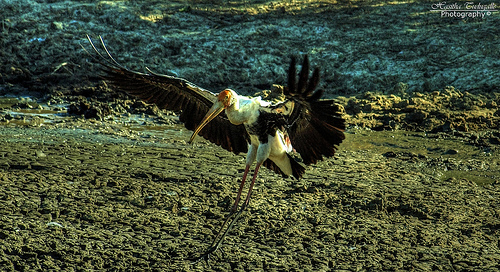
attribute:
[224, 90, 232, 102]
eye — black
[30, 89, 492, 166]
water — swirling, churning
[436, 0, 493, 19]
lettering — white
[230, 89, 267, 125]
patch — white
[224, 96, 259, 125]
chest — black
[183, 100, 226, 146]
beak — closed, long, pointy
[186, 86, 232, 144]
head — orange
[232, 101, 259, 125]
neck — white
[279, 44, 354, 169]
tail — black and white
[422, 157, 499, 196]
puddle — small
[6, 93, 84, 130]
water — shallow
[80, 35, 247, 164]
wing — curling up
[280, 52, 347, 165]
feathers — black, fan shaped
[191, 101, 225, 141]
beak — long, white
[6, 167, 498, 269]
ground — sand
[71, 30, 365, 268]
bird — large, mostly black, mostly white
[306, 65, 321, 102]
tail feather — dark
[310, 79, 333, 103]
tail feather — dark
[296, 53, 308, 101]
tail feather — dark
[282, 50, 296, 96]
tail feather — dark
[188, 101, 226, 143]
beak — long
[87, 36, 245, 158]
wing — long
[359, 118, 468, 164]
water — muddy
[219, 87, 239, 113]
head — orange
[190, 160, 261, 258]
leg — very long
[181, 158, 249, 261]
leg — very long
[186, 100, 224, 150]
beak — long